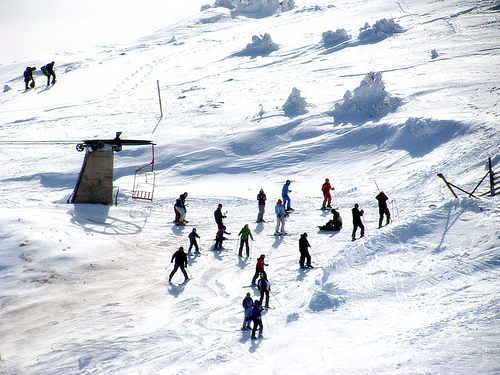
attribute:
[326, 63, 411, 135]
snow pile — large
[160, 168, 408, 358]
people — are skiing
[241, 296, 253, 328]
blue outifit — black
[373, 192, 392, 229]
person — is skiing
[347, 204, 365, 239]
person — is skiing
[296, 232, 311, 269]
person — is skiing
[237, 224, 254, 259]
person — is skiing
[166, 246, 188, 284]
person — is skiing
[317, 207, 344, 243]
person — is sitting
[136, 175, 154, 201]
chair — red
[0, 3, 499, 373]
snow — white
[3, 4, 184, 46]
sky — white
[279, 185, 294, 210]
outfit — blue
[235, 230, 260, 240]
jacket — green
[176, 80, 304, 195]
snow — white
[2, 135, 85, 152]
lift cable — black, metal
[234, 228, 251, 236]
jacket — green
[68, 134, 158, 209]
ski lift — broken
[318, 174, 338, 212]
outfit — red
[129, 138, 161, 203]
lift chair — red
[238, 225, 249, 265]
outfit — green